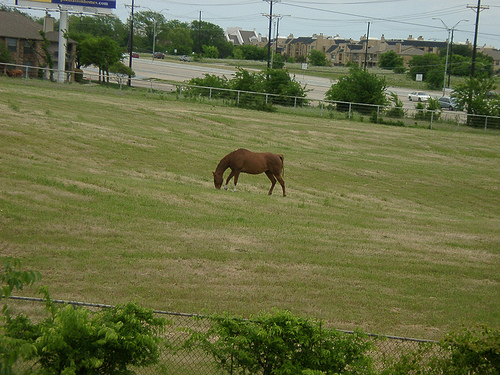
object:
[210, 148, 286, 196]
animal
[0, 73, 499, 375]
field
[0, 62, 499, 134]
fence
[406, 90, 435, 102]
cars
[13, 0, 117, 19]
sign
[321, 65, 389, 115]
bush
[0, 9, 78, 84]
buildings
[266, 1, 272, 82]
power pole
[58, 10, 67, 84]
pole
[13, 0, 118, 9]
billboard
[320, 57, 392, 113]
trees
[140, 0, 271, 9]
wires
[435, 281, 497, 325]
grass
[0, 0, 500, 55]
sky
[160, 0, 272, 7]
lines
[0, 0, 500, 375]
background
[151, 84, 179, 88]
wires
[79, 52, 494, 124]
highway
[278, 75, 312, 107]
bushes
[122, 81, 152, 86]
chain link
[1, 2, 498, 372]
scene